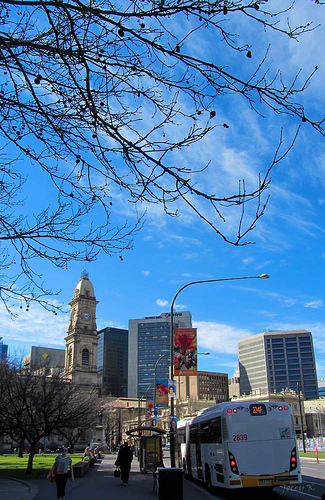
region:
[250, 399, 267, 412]
The marquee display on the back of the bus.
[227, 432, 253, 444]
The four digit number on the back of the bus.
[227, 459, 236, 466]
The left red light on the back of the bus.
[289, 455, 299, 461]
The right red light on the back of the bus.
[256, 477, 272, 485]
The license plate on the back of the bus.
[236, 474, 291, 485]
The yellow paint on the bumper of the bus.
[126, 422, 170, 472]
The bus stop sitting/waiting area.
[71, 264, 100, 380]
The big building with the clock on it.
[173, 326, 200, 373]
The red floral designed banner hanging on the street lamp post above the bus.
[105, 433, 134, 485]
The person walking on the sidewalk holding a black purse.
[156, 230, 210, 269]
this is the sky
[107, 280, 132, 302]
the sky is blue in color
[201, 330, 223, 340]
these are the clouds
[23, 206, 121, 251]
this is a tree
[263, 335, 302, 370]
this is a building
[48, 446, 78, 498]
this is a lady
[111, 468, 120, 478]
this is a handbag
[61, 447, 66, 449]
this is a spectacle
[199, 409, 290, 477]
this is a bus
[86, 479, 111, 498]
this is a road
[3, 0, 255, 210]
tree branches silhouetted against sky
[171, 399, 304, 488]
white public bus with yellow bumper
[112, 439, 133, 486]
woman in black walking down sidewalk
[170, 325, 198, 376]
orange and red banner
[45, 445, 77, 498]
woman carrying a bag walking down sidewalk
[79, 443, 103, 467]
people sitting on concrete bench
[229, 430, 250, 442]
red numbers on white bus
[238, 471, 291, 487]
yellow bumper on back of bus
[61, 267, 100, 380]
clock tower on a tall building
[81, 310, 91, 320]
clock face on a tower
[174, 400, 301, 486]
the bus is at the bus stop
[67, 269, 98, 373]
the tower has a clock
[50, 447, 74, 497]
the woman has black pants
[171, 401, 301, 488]
the bus is white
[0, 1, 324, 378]
the sky is cloudy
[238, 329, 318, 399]
the building has many windows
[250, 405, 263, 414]
the bus has number 224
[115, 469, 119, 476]
the person carries a bag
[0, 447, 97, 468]
the grass is green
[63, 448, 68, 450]
the person wears glasses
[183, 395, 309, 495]
Bus parked on side road is white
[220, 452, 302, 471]
Back lights are red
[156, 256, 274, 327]
Street pole is high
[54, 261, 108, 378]
Old tower in city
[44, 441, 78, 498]
Woman holding a bag on right shoulder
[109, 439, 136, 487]
Person carry a bag on right hand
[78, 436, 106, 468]
People sitting on benches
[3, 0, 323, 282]
Branches of trees do not have leaves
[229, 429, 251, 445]
Number on bus 2839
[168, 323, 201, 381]
Street banner hang from pole